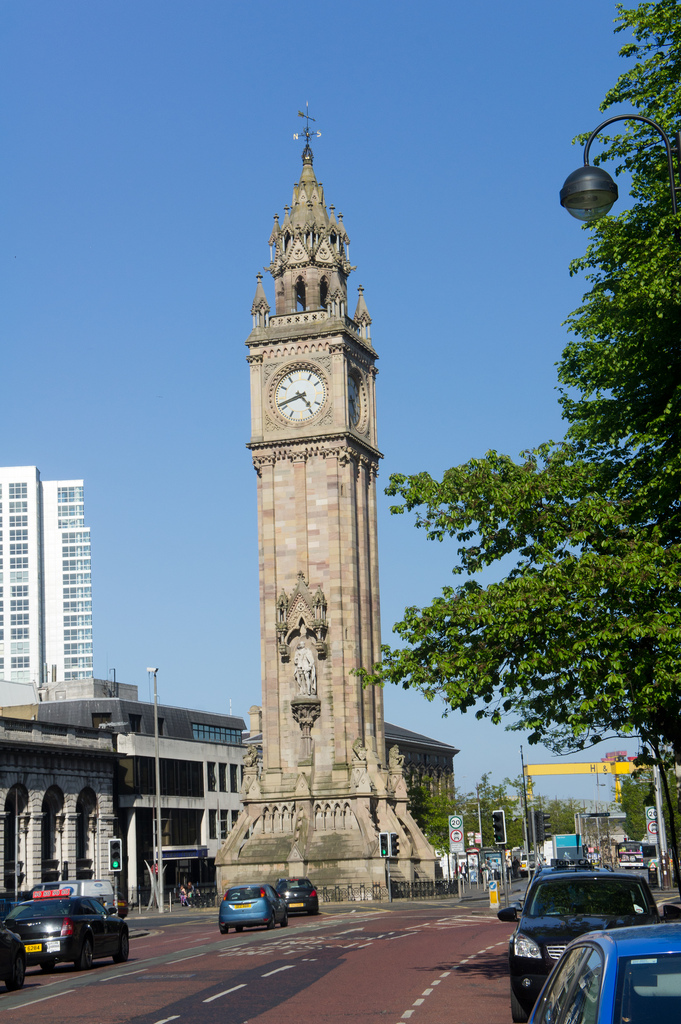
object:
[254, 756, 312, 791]
wall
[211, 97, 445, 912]
building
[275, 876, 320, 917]
car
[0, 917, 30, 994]
car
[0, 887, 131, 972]
car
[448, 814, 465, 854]
signs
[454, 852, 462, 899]
pole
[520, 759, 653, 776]
sign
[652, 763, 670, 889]
poles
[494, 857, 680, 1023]
car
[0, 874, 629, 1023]
road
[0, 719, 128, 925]
building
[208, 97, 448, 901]
large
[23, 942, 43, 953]
plate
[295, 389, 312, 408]
hands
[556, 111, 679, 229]
lights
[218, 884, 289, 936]
car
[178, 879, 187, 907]
people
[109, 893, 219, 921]
sidewalk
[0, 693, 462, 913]
buildings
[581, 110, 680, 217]
pole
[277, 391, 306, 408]
hands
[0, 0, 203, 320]
sky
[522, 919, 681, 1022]
car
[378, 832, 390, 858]
stoplight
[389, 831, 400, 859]
stoplight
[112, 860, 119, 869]
light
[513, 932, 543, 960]
headlight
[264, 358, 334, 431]
clock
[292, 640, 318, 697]
statue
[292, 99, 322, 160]
weather vane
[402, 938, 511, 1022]
line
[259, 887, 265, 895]
red light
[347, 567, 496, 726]
leaves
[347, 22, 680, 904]
tree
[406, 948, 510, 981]
shadow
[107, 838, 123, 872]
traffic light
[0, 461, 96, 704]
building